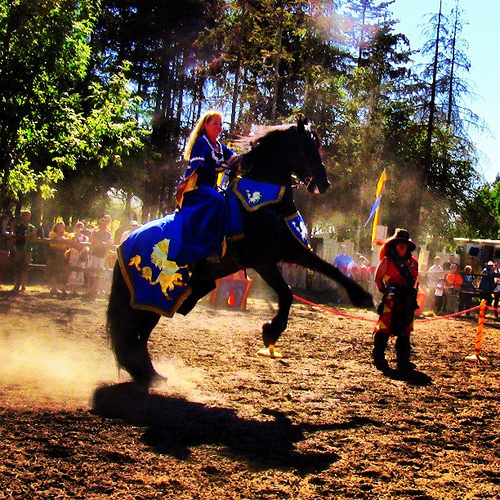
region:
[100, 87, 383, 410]
woman riding a black horse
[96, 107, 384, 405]
black horse wearing some clothing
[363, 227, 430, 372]
person standing in the dirt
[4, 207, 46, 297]
person standing behind a fence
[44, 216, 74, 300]
person standing behind a fence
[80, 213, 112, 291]
person standing behind a fence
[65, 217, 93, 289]
person standing behind a fence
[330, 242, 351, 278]
person standing behind a fence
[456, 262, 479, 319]
person standing behind a fence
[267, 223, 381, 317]
leg of the black horse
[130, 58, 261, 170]
face of the girl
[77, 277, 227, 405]
legs of the horse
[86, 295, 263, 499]
legs of the horse in sand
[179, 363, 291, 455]
shadow on the ground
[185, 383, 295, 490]
shadow of the horse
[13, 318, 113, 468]
dust raising from ground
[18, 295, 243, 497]
a horse raising the dust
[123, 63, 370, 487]
a girl raising up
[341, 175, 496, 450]
a girl standing near the horse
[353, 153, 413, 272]
a iron rod in the back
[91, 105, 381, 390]
woman riding horse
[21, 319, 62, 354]
dust in the air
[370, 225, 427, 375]
a man in costume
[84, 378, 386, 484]
shadow of the horse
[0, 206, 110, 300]
spectators behind the fence arena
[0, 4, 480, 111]
tall trees in the background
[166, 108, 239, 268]
a woman on horse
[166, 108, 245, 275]
a woman in costume riding horse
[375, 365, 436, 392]
shadow of the person standing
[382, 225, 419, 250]
hat on head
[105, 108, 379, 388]
woman riding a black horse on its hind legs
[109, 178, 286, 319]
blue and gold cape on horse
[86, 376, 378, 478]
shadow on ground cast by horse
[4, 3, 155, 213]
green leaves on trees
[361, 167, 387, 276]
blue and yellow flag on pole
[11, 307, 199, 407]
dirt in air kicked up by horse's feet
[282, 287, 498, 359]
red safety rope attached to yellow and red pole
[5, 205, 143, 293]
spectators behind wooden corral fence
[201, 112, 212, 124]
headband in woman's hair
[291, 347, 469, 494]
hoof prints in dirt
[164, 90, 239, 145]
face of the girl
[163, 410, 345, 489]
shadow on the ground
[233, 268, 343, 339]
legs of the horse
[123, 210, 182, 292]
a cloth in the horse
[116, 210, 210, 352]
a blue cloth in the horse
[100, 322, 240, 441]
back legs in the sand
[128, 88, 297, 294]
a girl sitting in horse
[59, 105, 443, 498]
a horse jumping into air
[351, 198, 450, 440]
a girl standing in ground